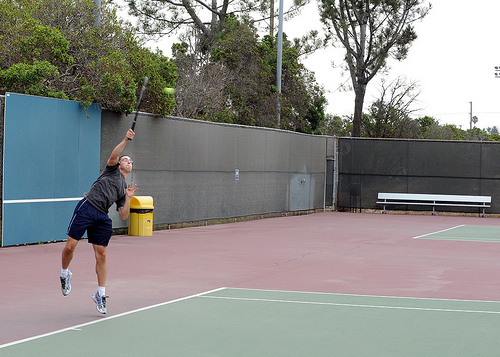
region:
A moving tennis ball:
[161, 85, 176, 95]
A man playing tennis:
[59, 81, 142, 313]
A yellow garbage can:
[128, 194, 153, 236]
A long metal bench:
[373, 188, 490, 216]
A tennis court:
[3, 216, 498, 353]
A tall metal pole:
[274, 0, 285, 127]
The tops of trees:
[324, 113, 497, 140]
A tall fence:
[6, 90, 338, 239]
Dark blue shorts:
[69, 199, 112, 246]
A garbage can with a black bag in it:
[126, 194, 153, 236]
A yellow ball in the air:
[162, 84, 177, 96]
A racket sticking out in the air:
[128, 75, 154, 128]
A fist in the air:
[124, 125, 136, 142]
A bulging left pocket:
[103, 215, 111, 231]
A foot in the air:
[58, 268, 73, 295]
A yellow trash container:
[131, 197, 153, 236]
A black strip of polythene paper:
[134, 206, 153, 213]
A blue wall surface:
[11, 99, 56, 189]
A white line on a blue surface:
[10, 197, 57, 203]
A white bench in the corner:
[373, 188, 493, 213]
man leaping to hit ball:
[46, 80, 178, 313]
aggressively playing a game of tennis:
[55, 72, 191, 311]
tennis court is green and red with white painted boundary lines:
[143, 277, 375, 353]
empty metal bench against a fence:
[375, 188, 495, 219]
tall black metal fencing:
[340, 131, 376, 216]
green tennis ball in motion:
[164, 85, 173, 97]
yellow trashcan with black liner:
[131, 191, 153, 236]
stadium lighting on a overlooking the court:
[490, 62, 498, 78]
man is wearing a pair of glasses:
[112, 153, 134, 173]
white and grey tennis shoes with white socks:
[55, 272, 112, 314]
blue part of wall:
[2, 90, 111, 242]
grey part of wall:
[101, 120, 335, 217]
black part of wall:
[344, 138, 498, 214]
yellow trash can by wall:
[129, 193, 157, 235]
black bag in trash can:
[127, 205, 154, 211]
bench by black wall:
[380, 191, 487, 213]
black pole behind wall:
[277, 0, 282, 116]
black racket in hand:
[131, 85, 154, 128]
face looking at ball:
[120, 150, 133, 170]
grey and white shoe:
[58, 265, 68, 293]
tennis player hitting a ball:
[44, 66, 196, 316]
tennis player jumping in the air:
[53, 70, 189, 322]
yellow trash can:
[127, 183, 155, 238]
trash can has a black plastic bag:
[126, 185, 162, 237]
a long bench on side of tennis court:
[368, 187, 494, 218]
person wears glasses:
[83, 116, 146, 186]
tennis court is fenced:
[9, 84, 497, 355]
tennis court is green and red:
[0, 205, 487, 355]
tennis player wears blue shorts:
[57, 125, 140, 316]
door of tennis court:
[318, 145, 338, 212]